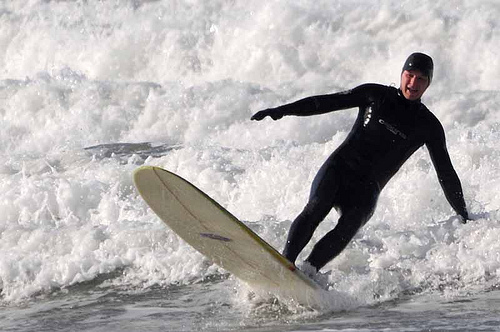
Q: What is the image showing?
A: It is showing an ocean.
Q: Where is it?
A: This is at the ocean.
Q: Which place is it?
A: It is an ocean.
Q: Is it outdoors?
A: Yes, it is outdoors.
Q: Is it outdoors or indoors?
A: It is outdoors.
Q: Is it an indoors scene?
A: No, it is outdoors.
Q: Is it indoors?
A: No, it is outdoors.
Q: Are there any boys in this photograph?
A: No, there are no boys.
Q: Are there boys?
A: No, there are no boys.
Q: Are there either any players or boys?
A: No, there are no boys or players.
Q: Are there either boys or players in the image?
A: No, there are no boys or players.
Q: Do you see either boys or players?
A: No, there are no boys or players.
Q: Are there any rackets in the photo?
A: No, there are no rackets.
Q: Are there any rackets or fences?
A: No, there are no rackets or fences.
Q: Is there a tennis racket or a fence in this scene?
A: No, there are no rackets or fences.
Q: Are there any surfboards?
A: Yes, there is a surfboard.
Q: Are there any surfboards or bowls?
A: Yes, there is a surfboard.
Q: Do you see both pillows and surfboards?
A: No, there is a surfboard but no pillows.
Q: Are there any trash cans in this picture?
A: No, there are no trash cans.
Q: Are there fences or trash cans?
A: No, there are no trash cans or fences.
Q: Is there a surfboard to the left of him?
A: Yes, there is a surfboard to the left of the man.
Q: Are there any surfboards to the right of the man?
A: No, the surfboard is to the left of the man.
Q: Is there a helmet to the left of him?
A: No, there is a surfboard to the left of the man.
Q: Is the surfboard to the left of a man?
A: Yes, the surfboard is to the left of a man.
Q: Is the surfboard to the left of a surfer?
A: No, the surfboard is to the left of a man.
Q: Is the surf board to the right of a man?
A: No, the surf board is to the left of a man.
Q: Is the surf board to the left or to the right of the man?
A: The surf board is to the left of the man.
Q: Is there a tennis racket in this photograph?
A: No, there are no rackets.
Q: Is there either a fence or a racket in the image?
A: No, there are no rackets or fences.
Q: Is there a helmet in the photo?
A: No, there are no helmets.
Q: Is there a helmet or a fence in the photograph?
A: No, there are no helmets or fences.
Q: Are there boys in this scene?
A: No, there are no boys.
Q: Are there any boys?
A: No, there are no boys.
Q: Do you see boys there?
A: No, there are no boys.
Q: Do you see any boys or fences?
A: No, there are no boys or fences.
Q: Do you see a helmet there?
A: No, there are no helmets.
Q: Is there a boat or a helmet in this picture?
A: No, there are no helmets or boats.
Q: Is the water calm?
A: Yes, the water is calm.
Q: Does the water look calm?
A: Yes, the water is calm.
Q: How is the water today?
A: The water is calm.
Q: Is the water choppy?
A: No, the water is calm.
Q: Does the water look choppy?
A: No, the water is calm.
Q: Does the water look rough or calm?
A: The water is calm.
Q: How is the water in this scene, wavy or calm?
A: The water is calm.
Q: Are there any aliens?
A: No, there are no aliens.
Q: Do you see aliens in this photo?
A: No, there are no aliens.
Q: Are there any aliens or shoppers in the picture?
A: No, there are no aliens or shoppers.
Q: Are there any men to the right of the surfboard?
A: Yes, there is a man to the right of the surfboard.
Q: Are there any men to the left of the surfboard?
A: No, the man is to the right of the surfboard.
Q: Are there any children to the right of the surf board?
A: No, there is a man to the right of the surf board.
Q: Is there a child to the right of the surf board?
A: No, there is a man to the right of the surf board.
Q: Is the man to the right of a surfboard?
A: Yes, the man is to the right of a surfboard.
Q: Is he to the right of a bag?
A: No, the man is to the right of a surfboard.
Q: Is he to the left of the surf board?
A: No, the man is to the right of the surf board.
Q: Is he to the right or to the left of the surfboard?
A: The man is to the right of the surfboard.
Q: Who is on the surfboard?
A: The man is on the surfboard.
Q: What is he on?
A: The man is on the surf board.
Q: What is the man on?
A: The man is on the surf board.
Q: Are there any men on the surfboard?
A: Yes, there is a man on the surfboard.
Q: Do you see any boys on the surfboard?
A: No, there is a man on the surfboard.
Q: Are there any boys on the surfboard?
A: No, there is a man on the surfboard.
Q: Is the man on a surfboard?
A: Yes, the man is on a surfboard.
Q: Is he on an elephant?
A: No, the man is on a surfboard.